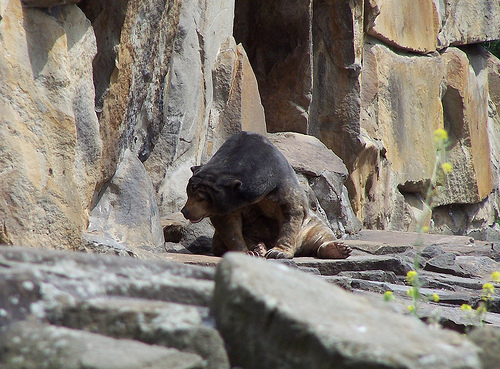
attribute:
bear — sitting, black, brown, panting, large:
[157, 131, 353, 266]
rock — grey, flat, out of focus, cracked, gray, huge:
[0, 2, 497, 367]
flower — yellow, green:
[381, 124, 499, 326]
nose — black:
[180, 204, 201, 225]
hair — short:
[187, 129, 292, 179]